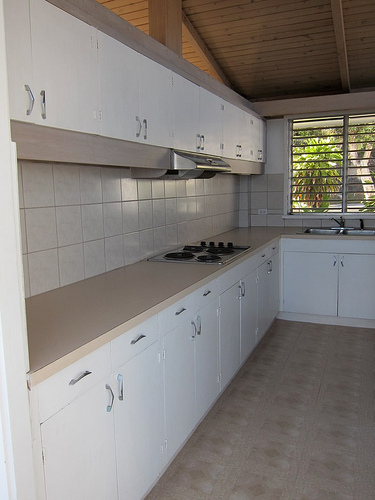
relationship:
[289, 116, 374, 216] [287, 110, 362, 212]
window with slats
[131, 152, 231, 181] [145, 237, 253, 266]
hood over stovetop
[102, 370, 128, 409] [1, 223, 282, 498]
handles on cabinet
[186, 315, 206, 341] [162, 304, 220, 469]
handles on cabinet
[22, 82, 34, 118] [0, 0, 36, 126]
handle of cabinet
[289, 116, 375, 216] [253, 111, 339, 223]
window on wall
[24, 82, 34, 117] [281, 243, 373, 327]
handle on cabinet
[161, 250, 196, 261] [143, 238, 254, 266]
burner on cook top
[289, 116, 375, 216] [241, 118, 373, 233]
window on wall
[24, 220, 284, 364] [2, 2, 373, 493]
beige counter on kitchen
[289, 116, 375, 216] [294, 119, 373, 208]
window with blinds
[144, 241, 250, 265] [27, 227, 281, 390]
stove set into beige counter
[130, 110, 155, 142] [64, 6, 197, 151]
handles on cabinet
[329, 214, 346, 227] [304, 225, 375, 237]
faucet on double sink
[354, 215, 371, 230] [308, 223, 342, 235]
sprayer on sink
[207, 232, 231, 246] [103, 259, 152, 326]
knobs on counter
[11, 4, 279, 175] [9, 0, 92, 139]
row of cabinet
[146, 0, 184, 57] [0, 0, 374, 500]
beam in kitchen